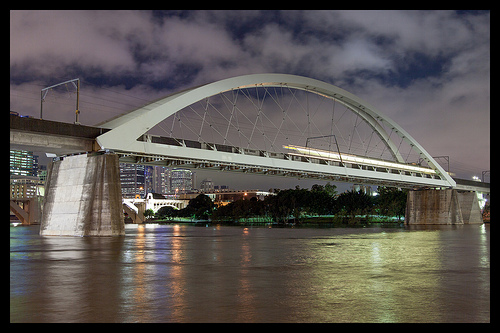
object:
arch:
[94, 72, 456, 186]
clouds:
[70, 29, 148, 88]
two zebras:
[90, 61, 462, 192]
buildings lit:
[11, 152, 22, 169]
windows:
[171, 171, 189, 187]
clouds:
[322, 25, 457, 112]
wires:
[227, 100, 337, 155]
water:
[140, 225, 448, 312]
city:
[146, 199, 179, 211]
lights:
[471, 175, 488, 211]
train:
[282, 144, 456, 179]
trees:
[334, 185, 408, 216]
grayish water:
[10, 223, 489, 319]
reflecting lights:
[135, 224, 143, 271]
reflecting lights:
[172, 225, 182, 289]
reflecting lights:
[372, 225, 381, 272]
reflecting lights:
[479, 224, 487, 264]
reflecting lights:
[242, 225, 249, 279]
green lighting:
[157, 212, 406, 225]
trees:
[185, 188, 408, 212]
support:
[39, 149, 126, 238]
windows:
[124, 165, 139, 183]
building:
[119, 157, 154, 199]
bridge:
[38, 73, 484, 237]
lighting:
[132, 221, 153, 253]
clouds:
[6, 16, 136, 78]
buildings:
[165, 166, 196, 195]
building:
[5, 149, 39, 210]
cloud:
[146, 14, 251, 74]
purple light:
[152, 224, 170, 321]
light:
[319, 234, 419, 320]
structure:
[39, 77, 83, 125]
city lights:
[11, 155, 180, 209]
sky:
[9, 10, 491, 65]